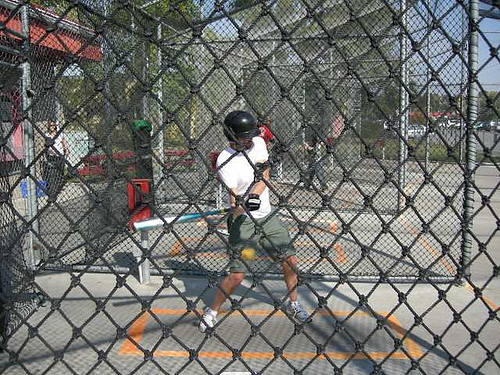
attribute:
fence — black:
[96, 36, 251, 98]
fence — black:
[61, 15, 159, 110]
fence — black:
[3, 2, 499, 372]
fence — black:
[181, 13, 211, 47]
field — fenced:
[0, 157, 497, 370]